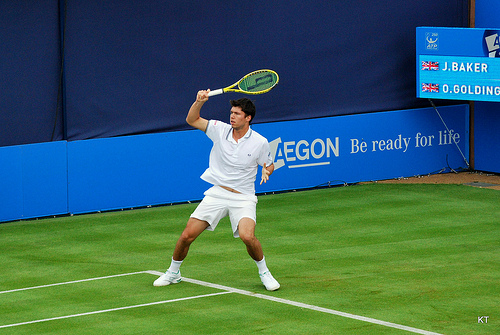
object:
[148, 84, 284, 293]
man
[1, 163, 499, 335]
court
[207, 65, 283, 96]
racket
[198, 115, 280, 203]
shirt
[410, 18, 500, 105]
scoreboard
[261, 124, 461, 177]
sign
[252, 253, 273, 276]
sock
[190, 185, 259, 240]
shorts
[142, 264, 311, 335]
line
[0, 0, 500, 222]
wall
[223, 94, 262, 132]
head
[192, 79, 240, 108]
handle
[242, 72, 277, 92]
initial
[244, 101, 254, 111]
hair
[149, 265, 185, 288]
shoe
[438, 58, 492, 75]
word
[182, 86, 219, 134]
arm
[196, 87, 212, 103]
hand